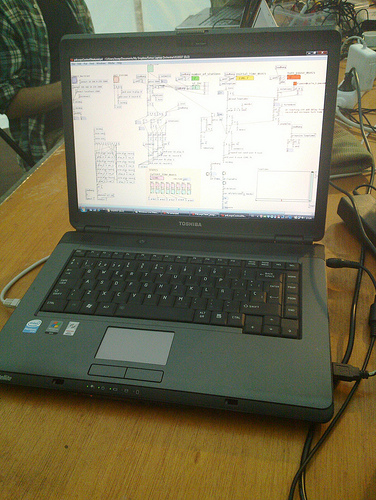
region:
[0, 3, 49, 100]
open plaid shirt on man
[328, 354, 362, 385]
cable in side of laptop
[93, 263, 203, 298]
letters on computer keyboard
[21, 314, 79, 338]
three stickers on laptop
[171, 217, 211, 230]
name of computer maker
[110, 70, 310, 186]
diagram on computer screen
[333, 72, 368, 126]
cords plugged into powerstrip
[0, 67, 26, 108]
rolled up sleeve on arm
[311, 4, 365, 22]
tangled black pile of wires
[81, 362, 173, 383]
left and right buttons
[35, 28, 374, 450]
Laptop on a desk.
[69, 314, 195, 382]
Mouse pad on the lap top.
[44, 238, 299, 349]
Keys on the lap top.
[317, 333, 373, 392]
Cord in the lap top.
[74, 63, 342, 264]
Screen of the lap top.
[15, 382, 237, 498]
Wooden desk under the lap top.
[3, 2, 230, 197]
Person behind the desk.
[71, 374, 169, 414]
Lights on the lap top.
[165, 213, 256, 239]
brand on the lap top.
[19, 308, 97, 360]
Labels on the lap top.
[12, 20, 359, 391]
open laptop on table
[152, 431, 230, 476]
wood grain on table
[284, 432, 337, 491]
black cables on table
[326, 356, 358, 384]
black cable in USB port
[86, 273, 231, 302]
letters on laptop keyboard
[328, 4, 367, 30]
tangled black computer wires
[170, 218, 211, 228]
name of computer company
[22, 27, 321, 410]
dark grey laptop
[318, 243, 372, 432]
black cords plugged into laptop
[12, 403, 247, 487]
table appears to be wooden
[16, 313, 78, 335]
brand stickers on laptop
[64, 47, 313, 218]
document displayed on laptop screen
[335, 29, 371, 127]
cords plugged into white surge protector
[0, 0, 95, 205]
person standing near table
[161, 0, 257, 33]
laptop in background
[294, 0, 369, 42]
tangle of cords in background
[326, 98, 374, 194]
what appears to be an article of clothing on table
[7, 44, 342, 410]
grey laptop with top lifted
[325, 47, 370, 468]
cords and wires by laptop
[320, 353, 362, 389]
plug inserted into side of laptop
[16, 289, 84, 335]
logos below keyboard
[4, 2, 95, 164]
person in plaid shirt behind laptop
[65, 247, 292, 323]
white print on black keys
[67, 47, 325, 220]
diagram on laptop screen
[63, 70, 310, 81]
row of colored boxes across top of diagram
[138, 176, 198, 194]
pink and blue repeated pattern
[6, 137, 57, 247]
wooden desk with metal edging